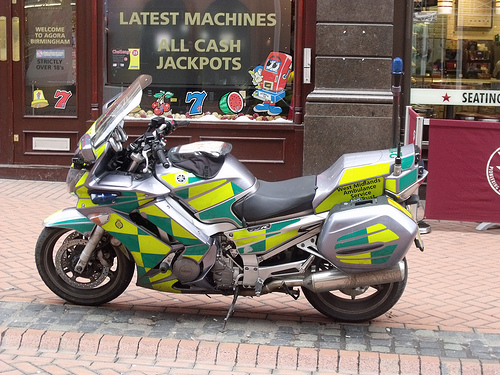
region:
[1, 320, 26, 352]
red brick on road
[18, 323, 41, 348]
red brick on road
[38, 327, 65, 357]
red brick on road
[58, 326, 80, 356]
red brick on road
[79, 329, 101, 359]
red brick on road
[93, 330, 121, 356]
red brick on road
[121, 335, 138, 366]
red brick on road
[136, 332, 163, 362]
red brick on road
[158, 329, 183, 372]
red brick on road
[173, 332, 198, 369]
red brick on road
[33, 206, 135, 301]
front tire of bike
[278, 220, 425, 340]
back tire of the bike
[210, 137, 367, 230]
seat on the bike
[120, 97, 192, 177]
handlebars on the bike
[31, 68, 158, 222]
front part of the bike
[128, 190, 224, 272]
yellow and green bike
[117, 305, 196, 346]
gray ground in photo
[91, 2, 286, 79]
words on the mirror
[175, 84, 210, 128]
the number 7 in blue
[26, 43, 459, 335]
bike with no one on it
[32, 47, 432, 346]
The motorcycle is colorful.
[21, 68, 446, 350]
The motorcycle is green, yellow and silver.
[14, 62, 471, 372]
The motorcycle is parked on the sidewalk.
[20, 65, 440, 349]
The motorcycle is leaning on the kickstand.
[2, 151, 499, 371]
The sidewalk is bricked.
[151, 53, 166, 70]
The letter is tan.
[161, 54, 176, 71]
The letter is tan.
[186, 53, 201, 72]
The letter is tan.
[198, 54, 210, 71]
The letter is tan.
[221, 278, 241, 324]
kick stand on a motorcycle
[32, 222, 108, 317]
a tire on a bike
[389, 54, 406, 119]
a light on the bike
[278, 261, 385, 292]
a muffler on a bike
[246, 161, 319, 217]
a seat on the bike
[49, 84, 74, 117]
a number on the window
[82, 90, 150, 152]
a windshield on a bike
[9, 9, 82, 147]
a door to a store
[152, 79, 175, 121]
cherries on a window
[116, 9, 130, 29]
The letter is tan.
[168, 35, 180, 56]
The letter is tan.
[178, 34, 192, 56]
The letter is tan.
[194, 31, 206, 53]
The letter is tan.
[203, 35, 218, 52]
The letter is tan.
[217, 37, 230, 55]
The letter is tan.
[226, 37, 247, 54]
The letter is tan.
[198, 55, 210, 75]
The letter is tan.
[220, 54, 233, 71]
The letter is tan.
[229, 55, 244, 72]
The letter is tan.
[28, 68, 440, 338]
a motorcycle parked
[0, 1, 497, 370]
a scene during the day time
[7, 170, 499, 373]
a pink and gray brick ground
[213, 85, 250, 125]
an image of a watermelon